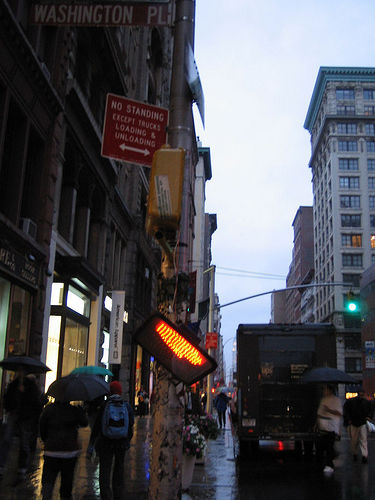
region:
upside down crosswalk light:
[130, 303, 229, 395]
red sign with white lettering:
[95, 85, 173, 172]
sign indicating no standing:
[98, 87, 170, 169]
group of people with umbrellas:
[0, 342, 114, 496]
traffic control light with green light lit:
[342, 282, 361, 318]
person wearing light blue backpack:
[87, 375, 138, 497]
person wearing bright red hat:
[94, 373, 144, 498]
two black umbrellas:
[0, 349, 114, 412]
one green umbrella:
[69, 352, 119, 385]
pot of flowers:
[178, 418, 216, 498]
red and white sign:
[89, 91, 169, 173]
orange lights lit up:
[132, 310, 211, 395]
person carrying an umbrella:
[30, 368, 102, 498]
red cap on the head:
[108, 380, 121, 393]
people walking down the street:
[5, 346, 236, 498]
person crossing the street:
[297, 362, 344, 480]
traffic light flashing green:
[342, 281, 359, 313]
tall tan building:
[295, 61, 374, 411]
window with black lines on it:
[335, 173, 363, 191]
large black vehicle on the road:
[228, 317, 346, 465]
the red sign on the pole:
[104, 90, 164, 167]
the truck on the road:
[234, 323, 340, 454]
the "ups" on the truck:
[259, 362, 275, 375]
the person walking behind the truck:
[303, 360, 352, 480]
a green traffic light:
[344, 302, 359, 312]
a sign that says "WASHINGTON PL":
[24, 4, 171, 24]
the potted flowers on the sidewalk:
[184, 409, 220, 487]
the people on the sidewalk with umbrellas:
[7, 347, 108, 494]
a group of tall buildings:
[268, 62, 372, 320]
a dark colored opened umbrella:
[46, 370, 110, 400]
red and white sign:
[111, 99, 202, 177]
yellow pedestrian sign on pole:
[143, 125, 195, 274]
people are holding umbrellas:
[16, 341, 136, 484]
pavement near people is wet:
[178, 414, 262, 491]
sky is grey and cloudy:
[212, 10, 286, 230]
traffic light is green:
[349, 299, 366, 335]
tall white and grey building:
[285, 69, 372, 300]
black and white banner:
[94, 281, 136, 371]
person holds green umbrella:
[71, 350, 114, 377]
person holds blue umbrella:
[37, 371, 99, 405]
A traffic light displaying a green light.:
[345, 288, 357, 314]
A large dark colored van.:
[234, 321, 340, 452]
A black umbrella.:
[49, 374, 108, 400]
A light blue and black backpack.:
[102, 395, 129, 439]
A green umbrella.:
[72, 364, 112, 376]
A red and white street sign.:
[100, 91, 171, 171]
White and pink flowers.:
[181, 411, 219, 457]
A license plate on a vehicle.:
[241, 418, 254, 427]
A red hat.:
[107, 378, 123, 395]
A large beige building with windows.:
[299, 65, 372, 465]